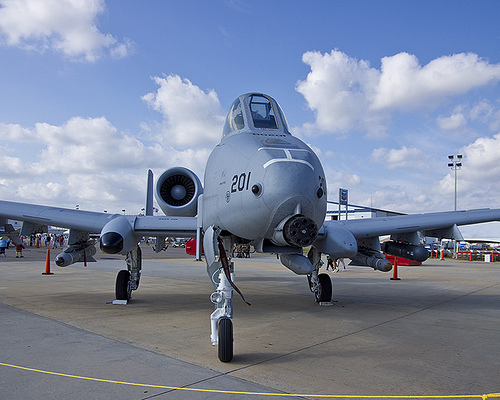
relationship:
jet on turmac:
[0, 90, 500, 368] [53, 303, 313, 396]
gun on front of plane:
[280, 211, 321, 248] [8, 90, 484, 370]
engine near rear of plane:
[153, 165, 201, 217] [8, 90, 484, 370]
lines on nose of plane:
[256, 147, 317, 171] [8, 90, 484, 370]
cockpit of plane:
[224, 91, 291, 135] [8, 90, 484, 370]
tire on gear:
[214, 317, 239, 364] [189, 233, 258, 371]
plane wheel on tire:
[314, 273, 333, 304] [217, 317, 234, 363]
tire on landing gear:
[114, 267, 131, 304] [113, 244, 143, 301]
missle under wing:
[371, 243, 439, 275] [336, 208, 461, 256]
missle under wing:
[52, 237, 98, 270] [0, 196, 197, 256]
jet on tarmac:
[0, 90, 500, 368] [6, 294, 498, 390]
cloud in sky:
[2, 0, 134, 61] [3, 1, 499, 242]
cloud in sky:
[142, 74, 224, 148] [3, 1, 499, 242]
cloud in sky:
[295, 50, 376, 137] [3, 1, 499, 242]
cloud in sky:
[375, 51, 495, 106] [3, 1, 499, 242]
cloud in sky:
[440, 114, 464, 132] [3, 1, 499, 242]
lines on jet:
[258, 143, 323, 171] [0, 90, 500, 368]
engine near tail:
[153, 165, 201, 217] [13, 189, 232, 310]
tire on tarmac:
[217, 317, 234, 363] [47, 303, 492, 393]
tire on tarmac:
[217, 317, 234, 363] [151, 313, 420, 387]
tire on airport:
[217, 317, 234, 363] [0, 240, 500, 400]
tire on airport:
[114, 267, 131, 304] [0, 240, 500, 400]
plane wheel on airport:
[314, 273, 333, 304] [0, 240, 500, 400]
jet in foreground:
[76, 64, 480, 361] [18, 67, 494, 377]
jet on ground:
[0, 90, 500, 368] [17, 265, 481, 375]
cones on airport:
[14, 242, 424, 292] [0, 240, 500, 400]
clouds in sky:
[2, 73, 228, 217] [3, 1, 499, 242]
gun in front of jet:
[286, 217, 319, 247] [2, 70, 497, 364]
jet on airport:
[0, 90, 500, 368] [19, 183, 484, 372]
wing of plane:
[0, 200, 199, 263] [8, 90, 484, 370]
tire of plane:
[217, 317, 234, 363] [7, 49, 479, 395]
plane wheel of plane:
[319, 270, 334, 307] [8, 90, 484, 370]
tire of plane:
[114, 267, 131, 304] [8, 90, 484, 370]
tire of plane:
[217, 317, 234, 363] [8, 90, 484, 370]